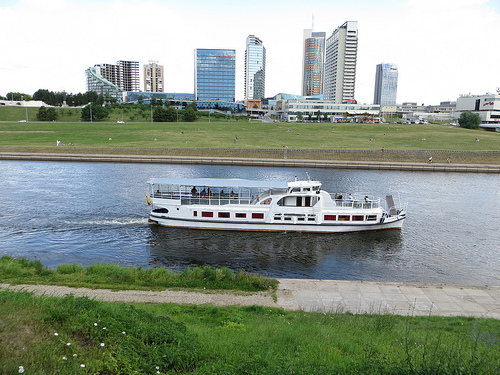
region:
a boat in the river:
[140, 166, 432, 251]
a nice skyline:
[68, 28, 451, 113]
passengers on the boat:
[181, 186, 249, 199]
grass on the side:
[152, 314, 339, 356]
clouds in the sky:
[22, 10, 84, 78]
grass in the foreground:
[67, 116, 384, 148]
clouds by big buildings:
[376, 0, 468, 52]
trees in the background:
[35, 86, 85, 130]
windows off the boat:
[320, 210, 376, 223]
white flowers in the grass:
[49, 321, 114, 373]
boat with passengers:
[140, 183, 421, 248]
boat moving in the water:
[75, 173, 460, 274]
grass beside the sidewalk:
[31, 302, 466, 368]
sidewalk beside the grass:
[27, 277, 485, 319]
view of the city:
[45, 52, 481, 129]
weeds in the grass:
[43, 310, 160, 366]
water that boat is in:
[20, 171, 141, 257]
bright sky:
[25, 12, 81, 62]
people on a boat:
[182, 180, 242, 201]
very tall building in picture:
[299, 21, 326, 112]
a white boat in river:
[124, 156, 441, 257]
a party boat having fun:
[118, 149, 430, 259]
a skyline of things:
[136, 24, 494, 121]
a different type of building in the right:
[433, 78, 498, 160]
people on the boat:
[189, 191, 238, 201]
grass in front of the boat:
[115, 311, 260, 368]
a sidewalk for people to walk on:
[327, 278, 467, 323]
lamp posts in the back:
[55, 86, 248, 128]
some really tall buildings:
[281, 6, 428, 123]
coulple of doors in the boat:
[295, 192, 314, 205]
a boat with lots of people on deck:
[55, 65, 451, 237]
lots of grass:
[45, 218, 402, 367]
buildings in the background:
[61, 47, 473, 185]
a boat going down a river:
[115, 99, 494, 294]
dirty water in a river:
[33, 153, 368, 362]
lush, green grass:
[53, 233, 338, 373]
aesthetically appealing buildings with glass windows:
[60, 41, 480, 217]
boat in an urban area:
[0, 5, 471, 317]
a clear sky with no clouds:
[28, 20, 482, 157]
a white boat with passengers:
[51, 119, 474, 314]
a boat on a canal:
[132, 165, 426, 245]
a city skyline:
[65, 11, 465, 147]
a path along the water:
[65, 262, 477, 331]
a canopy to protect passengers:
[145, 166, 281, 198]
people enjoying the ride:
[329, 185, 410, 211]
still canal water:
[31, 182, 94, 236]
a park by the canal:
[27, 105, 382, 145]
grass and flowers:
[23, 299, 178, 367]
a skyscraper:
[242, 25, 266, 102]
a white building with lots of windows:
[270, 97, 398, 126]